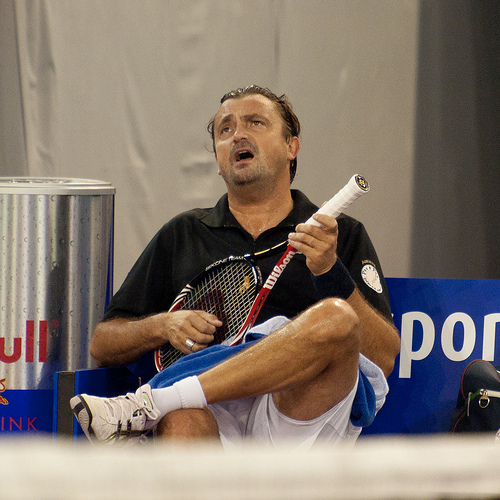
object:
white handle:
[305, 174, 371, 227]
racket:
[153, 172, 372, 374]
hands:
[287, 213, 339, 276]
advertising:
[398, 311, 499, 380]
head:
[205, 85, 301, 202]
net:
[224, 267, 249, 311]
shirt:
[99, 188, 398, 385]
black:
[79, 402, 86, 409]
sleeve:
[348, 218, 396, 325]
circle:
[360, 264, 383, 294]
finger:
[175, 340, 194, 355]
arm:
[88, 227, 173, 369]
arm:
[312, 230, 402, 381]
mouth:
[232, 146, 255, 164]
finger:
[177, 332, 207, 353]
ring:
[184, 338, 196, 350]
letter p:
[398, 310, 436, 379]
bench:
[1, 432, 497, 498]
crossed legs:
[66, 294, 368, 440]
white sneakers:
[69, 382, 164, 446]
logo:
[0, 319, 49, 436]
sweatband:
[310, 257, 356, 302]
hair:
[204, 84, 301, 187]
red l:
[38, 319, 48, 362]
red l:
[25, 319, 35, 362]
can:
[1, 179, 116, 432]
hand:
[165, 309, 223, 355]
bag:
[450, 358, 500, 431]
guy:
[68, 84, 403, 448]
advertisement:
[0, 318, 48, 432]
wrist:
[312, 251, 337, 277]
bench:
[51, 277, 499, 484]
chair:
[49, 276, 500, 445]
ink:
[54, 374, 73, 445]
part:
[25, 318, 46, 364]